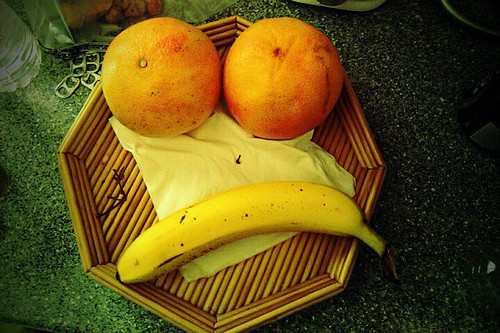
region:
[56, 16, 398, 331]
Oranges and banana in bowl.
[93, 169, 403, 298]
banana sitting in basket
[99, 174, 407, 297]
banana in basket is ripe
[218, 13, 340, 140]
orange on right side of basket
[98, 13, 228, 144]
orange on left side of basket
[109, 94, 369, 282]
napkin under the fruits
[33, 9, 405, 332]
basket holding napkin and fruit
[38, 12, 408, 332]
basket is wicker and brown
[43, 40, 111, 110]
small pile of can tabs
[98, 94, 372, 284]
napkin in basket is white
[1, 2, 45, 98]
water bottle in corner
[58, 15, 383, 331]
a wooden plate with fruit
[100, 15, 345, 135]
two fresh unpeeled grapefruits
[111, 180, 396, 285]
one very ripe banana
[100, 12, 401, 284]
two grapefruits and one banana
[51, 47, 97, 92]
a pile of soda can pull tabs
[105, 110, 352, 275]
a crumpled white napkin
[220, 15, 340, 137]
one fresh grapefruit with a bruise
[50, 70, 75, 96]
one silver soda can pull tab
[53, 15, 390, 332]
a wooden plate sitting on the counter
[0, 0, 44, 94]
an empty drinking glass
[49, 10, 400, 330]
this is a basket of fruit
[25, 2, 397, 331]
the basket is shaped like an octagon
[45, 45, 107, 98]
these are tabs from soda cans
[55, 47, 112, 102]
these are soda can tabs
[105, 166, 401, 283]
this is a banana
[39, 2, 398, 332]
the fruit is arranged to make a frowning face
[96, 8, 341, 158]
two large oranges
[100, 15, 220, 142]
this is an orange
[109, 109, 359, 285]
this is a napkin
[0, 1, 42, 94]
this is a plastic bottle of water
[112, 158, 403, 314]
a yelllow banana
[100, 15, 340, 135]
two round oranges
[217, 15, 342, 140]
one round orange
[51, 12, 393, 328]
two oranges and one banana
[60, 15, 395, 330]
a banana and two oranges and one paper towel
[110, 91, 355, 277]
one white paper towel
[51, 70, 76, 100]
one steel pull tab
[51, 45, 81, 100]
two steel pull tabs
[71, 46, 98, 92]
three steel pull tabs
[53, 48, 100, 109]
four steel pull tabs